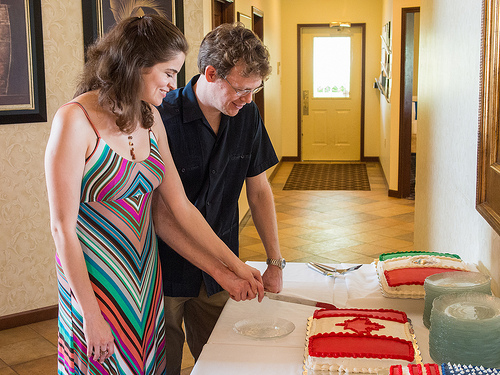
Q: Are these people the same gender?
A: No, they are both male and female.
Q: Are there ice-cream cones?
A: No, there are no ice-cream cones.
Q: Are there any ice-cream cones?
A: No, there are no ice-cream cones.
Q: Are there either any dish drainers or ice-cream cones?
A: No, there are no ice-cream cones or dish drainers.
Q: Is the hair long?
A: Yes, the hair is long.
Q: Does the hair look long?
A: Yes, the hair is long.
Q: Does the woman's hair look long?
A: Yes, the hair is long.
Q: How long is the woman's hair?
A: The hair is long.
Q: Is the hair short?
A: No, the hair is long.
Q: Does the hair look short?
A: No, the hair is long.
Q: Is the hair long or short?
A: The hair is long.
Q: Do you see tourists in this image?
A: No, there are no tourists.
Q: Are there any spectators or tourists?
A: No, there are no tourists or spectators.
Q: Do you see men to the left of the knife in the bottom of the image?
A: Yes, there is a man to the left of the knife.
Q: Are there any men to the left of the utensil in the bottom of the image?
A: Yes, there is a man to the left of the knife.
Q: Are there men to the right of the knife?
A: No, the man is to the left of the knife.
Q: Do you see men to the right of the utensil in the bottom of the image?
A: No, the man is to the left of the knife.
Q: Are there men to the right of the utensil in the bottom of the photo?
A: No, the man is to the left of the knife.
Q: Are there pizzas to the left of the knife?
A: No, there is a man to the left of the knife.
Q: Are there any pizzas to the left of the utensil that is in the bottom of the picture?
A: No, there is a man to the left of the knife.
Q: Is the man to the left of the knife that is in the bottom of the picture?
A: Yes, the man is to the left of the knife.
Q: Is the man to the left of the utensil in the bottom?
A: Yes, the man is to the left of the knife.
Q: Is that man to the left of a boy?
A: No, the man is to the left of the knife.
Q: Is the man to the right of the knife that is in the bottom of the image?
A: No, the man is to the left of the knife.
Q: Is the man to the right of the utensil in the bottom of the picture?
A: No, the man is to the left of the knife.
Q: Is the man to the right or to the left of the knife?
A: The man is to the left of the knife.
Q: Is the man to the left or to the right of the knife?
A: The man is to the left of the knife.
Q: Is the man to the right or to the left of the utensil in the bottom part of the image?
A: The man is to the left of the knife.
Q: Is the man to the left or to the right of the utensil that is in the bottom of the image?
A: The man is to the left of the knife.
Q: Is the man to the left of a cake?
A: Yes, the man is to the left of a cake.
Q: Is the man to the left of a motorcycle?
A: No, the man is to the left of a cake.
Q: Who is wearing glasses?
A: The man is wearing glasses.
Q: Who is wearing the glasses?
A: The man is wearing glasses.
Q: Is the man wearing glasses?
A: Yes, the man is wearing glasses.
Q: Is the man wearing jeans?
A: No, the man is wearing glasses.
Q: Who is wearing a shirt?
A: The man is wearing a shirt.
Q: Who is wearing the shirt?
A: The man is wearing a shirt.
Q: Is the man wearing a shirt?
A: Yes, the man is wearing a shirt.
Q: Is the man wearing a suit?
A: No, the man is wearing a shirt.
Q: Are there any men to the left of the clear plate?
A: Yes, there is a man to the left of the plate.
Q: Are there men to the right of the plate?
A: No, the man is to the left of the plate.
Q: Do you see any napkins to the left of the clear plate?
A: No, there is a man to the left of the plate.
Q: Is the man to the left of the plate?
A: Yes, the man is to the left of the plate.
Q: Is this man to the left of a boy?
A: No, the man is to the left of the plate.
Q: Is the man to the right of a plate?
A: No, the man is to the left of a plate.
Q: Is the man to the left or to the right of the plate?
A: The man is to the left of the plate.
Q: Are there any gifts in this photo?
A: No, there are no gifts.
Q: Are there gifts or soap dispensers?
A: No, there are no gifts or soap dispensers.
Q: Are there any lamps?
A: No, there are no lamps.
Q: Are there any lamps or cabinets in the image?
A: No, there are no lamps or cabinets.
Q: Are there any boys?
A: No, there are no boys.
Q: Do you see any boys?
A: No, there are no boys.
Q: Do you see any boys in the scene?
A: No, there are no boys.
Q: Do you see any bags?
A: No, there are no bags.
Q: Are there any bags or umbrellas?
A: No, there are no bags or umbrellas.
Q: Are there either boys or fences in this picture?
A: No, there are no boys or fences.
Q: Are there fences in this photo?
A: No, there are no fences.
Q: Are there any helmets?
A: No, there are no helmets.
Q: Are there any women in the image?
A: Yes, there is a woman.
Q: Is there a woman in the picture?
A: Yes, there is a woman.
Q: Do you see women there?
A: Yes, there is a woman.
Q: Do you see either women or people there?
A: Yes, there is a woman.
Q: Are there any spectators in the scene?
A: No, there are no spectators.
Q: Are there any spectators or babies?
A: No, there are no spectators or babies.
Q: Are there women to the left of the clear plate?
A: Yes, there is a woman to the left of the plate.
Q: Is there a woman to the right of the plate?
A: No, the woman is to the left of the plate.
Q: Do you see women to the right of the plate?
A: No, the woman is to the left of the plate.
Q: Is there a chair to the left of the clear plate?
A: No, there is a woman to the left of the plate.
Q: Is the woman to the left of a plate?
A: Yes, the woman is to the left of a plate.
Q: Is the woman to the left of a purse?
A: No, the woman is to the left of a plate.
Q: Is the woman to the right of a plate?
A: No, the woman is to the left of a plate.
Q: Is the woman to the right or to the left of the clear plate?
A: The woman is to the left of the plate.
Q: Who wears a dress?
A: The woman wears a dress.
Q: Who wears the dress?
A: The woman wears a dress.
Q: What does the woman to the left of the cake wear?
A: The woman wears a dress.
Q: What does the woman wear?
A: The woman wears a dress.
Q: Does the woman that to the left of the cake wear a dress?
A: Yes, the woman wears a dress.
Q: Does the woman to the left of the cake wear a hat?
A: No, the woman wears a dress.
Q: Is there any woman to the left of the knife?
A: Yes, there is a woman to the left of the knife.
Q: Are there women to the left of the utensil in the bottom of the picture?
A: Yes, there is a woman to the left of the knife.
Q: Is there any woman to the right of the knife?
A: No, the woman is to the left of the knife.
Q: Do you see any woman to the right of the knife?
A: No, the woman is to the left of the knife.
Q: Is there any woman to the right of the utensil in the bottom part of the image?
A: No, the woman is to the left of the knife.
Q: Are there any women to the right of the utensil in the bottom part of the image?
A: No, the woman is to the left of the knife.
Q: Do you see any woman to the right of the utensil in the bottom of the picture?
A: No, the woman is to the left of the knife.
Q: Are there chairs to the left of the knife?
A: No, there is a woman to the left of the knife.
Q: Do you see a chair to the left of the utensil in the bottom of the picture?
A: No, there is a woman to the left of the knife.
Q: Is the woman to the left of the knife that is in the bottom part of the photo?
A: Yes, the woman is to the left of the knife.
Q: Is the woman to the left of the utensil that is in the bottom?
A: Yes, the woman is to the left of the knife.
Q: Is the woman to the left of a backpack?
A: No, the woman is to the left of the knife.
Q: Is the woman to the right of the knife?
A: No, the woman is to the left of the knife.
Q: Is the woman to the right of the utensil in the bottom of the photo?
A: No, the woman is to the left of the knife.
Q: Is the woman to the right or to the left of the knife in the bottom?
A: The woman is to the left of the knife.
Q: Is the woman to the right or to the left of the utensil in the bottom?
A: The woman is to the left of the knife.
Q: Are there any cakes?
A: Yes, there is a cake.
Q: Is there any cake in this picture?
A: Yes, there is a cake.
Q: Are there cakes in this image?
A: Yes, there is a cake.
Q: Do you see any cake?
A: Yes, there is a cake.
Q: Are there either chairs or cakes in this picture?
A: Yes, there is a cake.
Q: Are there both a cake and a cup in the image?
A: No, there is a cake but no cups.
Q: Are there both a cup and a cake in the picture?
A: No, there is a cake but no cups.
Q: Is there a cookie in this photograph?
A: No, there are no cookies.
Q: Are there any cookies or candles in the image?
A: No, there are no cookies or candles.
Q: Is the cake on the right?
A: Yes, the cake is on the right of the image.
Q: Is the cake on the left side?
A: No, the cake is on the right of the image.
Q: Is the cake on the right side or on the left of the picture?
A: The cake is on the right of the image.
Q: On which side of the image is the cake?
A: The cake is on the right of the image.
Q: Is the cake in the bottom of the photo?
A: Yes, the cake is in the bottom of the image.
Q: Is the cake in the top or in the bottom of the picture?
A: The cake is in the bottom of the image.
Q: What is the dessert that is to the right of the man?
A: The dessert is a cake.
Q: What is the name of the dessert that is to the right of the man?
A: The dessert is a cake.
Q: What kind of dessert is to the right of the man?
A: The dessert is a cake.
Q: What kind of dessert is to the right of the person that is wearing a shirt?
A: The dessert is a cake.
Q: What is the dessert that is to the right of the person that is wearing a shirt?
A: The dessert is a cake.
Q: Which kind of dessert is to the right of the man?
A: The dessert is a cake.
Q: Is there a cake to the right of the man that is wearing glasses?
A: Yes, there is a cake to the right of the man.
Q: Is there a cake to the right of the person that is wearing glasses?
A: Yes, there is a cake to the right of the man.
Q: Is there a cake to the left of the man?
A: No, the cake is to the right of the man.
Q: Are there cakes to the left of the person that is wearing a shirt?
A: No, the cake is to the right of the man.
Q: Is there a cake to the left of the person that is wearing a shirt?
A: No, the cake is to the right of the man.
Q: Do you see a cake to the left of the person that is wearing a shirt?
A: No, the cake is to the right of the man.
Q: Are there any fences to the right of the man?
A: No, there is a cake to the right of the man.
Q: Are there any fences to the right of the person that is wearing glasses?
A: No, there is a cake to the right of the man.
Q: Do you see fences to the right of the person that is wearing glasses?
A: No, there is a cake to the right of the man.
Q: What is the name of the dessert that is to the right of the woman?
A: The dessert is a cake.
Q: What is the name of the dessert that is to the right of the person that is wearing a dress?
A: The dessert is a cake.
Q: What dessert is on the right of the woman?
A: The dessert is a cake.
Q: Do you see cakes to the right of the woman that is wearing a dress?
A: Yes, there is a cake to the right of the woman.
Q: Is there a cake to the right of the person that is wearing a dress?
A: Yes, there is a cake to the right of the woman.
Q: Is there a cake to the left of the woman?
A: No, the cake is to the right of the woman.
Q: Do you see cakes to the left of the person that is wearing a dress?
A: No, the cake is to the right of the woman.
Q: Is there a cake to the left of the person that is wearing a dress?
A: No, the cake is to the right of the woman.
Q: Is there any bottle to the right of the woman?
A: No, there is a cake to the right of the woman.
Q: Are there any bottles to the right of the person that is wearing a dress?
A: No, there is a cake to the right of the woman.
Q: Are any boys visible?
A: No, there are no boys.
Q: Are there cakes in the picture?
A: Yes, there is a cake.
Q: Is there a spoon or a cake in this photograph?
A: Yes, there is a cake.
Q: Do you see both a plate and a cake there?
A: Yes, there are both a cake and a plate.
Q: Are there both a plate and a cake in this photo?
A: Yes, there are both a cake and a plate.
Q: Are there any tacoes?
A: No, there are no tacoes.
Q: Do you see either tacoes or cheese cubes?
A: No, there are no tacoes or cheese cubes.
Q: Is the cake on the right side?
A: Yes, the cake is on the right of the image.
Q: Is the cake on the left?
A: No, the cake is on the right of the image.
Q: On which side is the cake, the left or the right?
A: The cake is on the right of the image.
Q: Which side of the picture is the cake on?
A: The cake is on the right of the image.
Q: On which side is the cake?
A: The cake is on the right of the image.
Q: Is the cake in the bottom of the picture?
A: Yes, the cake is in the bottom of the image.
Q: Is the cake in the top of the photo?
A: No, the cake is in the bottom of the image.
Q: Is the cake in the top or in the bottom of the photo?
A: The cake is in the bottom of the image.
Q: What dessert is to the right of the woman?
A: The dessert is a cake.